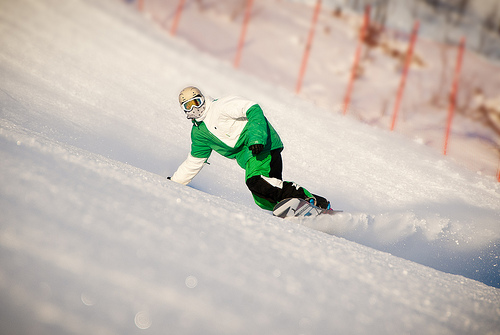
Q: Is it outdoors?
A: Yes, it is outdoors.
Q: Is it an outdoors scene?
A: Yes, it is outdoors.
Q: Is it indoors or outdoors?
A: It is outdoors.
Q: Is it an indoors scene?
A: No, it is outdoors.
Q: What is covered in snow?
A: The mountains are covered in snow.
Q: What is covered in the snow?
A: The mountains are covered in snow.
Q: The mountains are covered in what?
A: The mountains are covered in snow.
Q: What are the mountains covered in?
A: The mountains are covered in snow.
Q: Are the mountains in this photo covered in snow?
A: Yes, the mountains are covered in snow.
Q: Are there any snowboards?
A: Yes, there is a snowboard.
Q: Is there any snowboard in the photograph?
A: Yes, there is a snowboard.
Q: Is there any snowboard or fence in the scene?
A: Yes, there is a snowboard.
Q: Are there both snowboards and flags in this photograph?
A: No, there is a snowboard but no flags.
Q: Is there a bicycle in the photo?
A: No, there are no bicycles.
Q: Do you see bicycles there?
A: No, there are no bicycles.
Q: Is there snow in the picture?
A: Yes, there is snow.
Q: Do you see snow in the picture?
A: Yes, there is snow.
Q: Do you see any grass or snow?
A: Yes, there is snow.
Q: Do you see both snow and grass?
A: No, there is snow but no grass.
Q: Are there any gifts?
A: No, there are no gifts.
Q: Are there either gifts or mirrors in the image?
A: No, there are no gifts or mirrors.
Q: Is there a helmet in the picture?
A: Yes, there is a helmet.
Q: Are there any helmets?
A: Yes, there is a helmet.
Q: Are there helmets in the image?
A: Yes, there is a helmet.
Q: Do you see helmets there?
A: Yes, there is a helmet.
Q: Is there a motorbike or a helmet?
A: Yes, there is a helmet.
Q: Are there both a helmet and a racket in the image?
A: No, there is a helmet but no rackets.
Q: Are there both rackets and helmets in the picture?
A: No, there is a helmet but no rackets.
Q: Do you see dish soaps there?
A: No, there are no dish soaps.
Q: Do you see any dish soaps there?
A: No, there are no dish soaps.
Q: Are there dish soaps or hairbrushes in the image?
A: No, there are no dish soaps or hairbrushes.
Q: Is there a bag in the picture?
A: No, there are no bags.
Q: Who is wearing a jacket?
A: The man is wearing a jacket.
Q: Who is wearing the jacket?
A: The man is wearing a jacket.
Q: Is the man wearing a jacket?
A: Yes, the man is wearing a jacket.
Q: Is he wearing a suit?
A: No, the man is wearing a jacket.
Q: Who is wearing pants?
A: The man is wearing pants.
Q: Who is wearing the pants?
A: The man is wearing pants.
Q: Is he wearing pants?
A: Yes, the man is wearing pants.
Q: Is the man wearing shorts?
A: No, the man is wearing pants.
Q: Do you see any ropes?
A: No, there are no ropes.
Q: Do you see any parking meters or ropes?
A: No, there are no ropes or parking meters.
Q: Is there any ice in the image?
A: Yes, there is ice.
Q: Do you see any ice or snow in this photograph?
A: Yes, there is ice.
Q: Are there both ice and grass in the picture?
A: No, there is ice but no grass.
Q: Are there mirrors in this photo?
A: No, there are no mirrors.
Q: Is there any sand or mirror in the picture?
A: No, there are no mirrors or sand.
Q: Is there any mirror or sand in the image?
A: No, there are no mirrors or sand.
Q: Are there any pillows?
A: No, there are no pillows.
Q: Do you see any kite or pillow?
A: No, there are no pillows or kites.